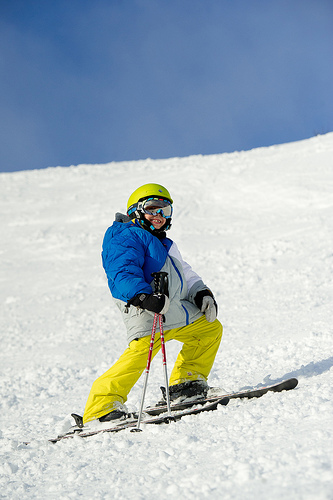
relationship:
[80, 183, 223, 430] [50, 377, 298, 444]
boy standing on skis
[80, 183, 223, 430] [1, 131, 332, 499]
boy in snow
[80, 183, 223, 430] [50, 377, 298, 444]
boy on skis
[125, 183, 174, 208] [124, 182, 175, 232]
helmet on head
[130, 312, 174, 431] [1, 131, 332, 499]
poles in snow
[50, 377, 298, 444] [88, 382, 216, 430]
skis attached to feet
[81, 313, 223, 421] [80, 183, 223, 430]
pants on boy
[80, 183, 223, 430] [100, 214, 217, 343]
boy wearing jacket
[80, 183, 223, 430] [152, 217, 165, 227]
boy has smile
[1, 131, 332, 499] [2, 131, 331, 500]
snow on ground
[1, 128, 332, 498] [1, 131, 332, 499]
hill covered with snow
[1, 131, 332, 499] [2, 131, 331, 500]
snow covering ground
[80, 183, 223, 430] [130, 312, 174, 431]
boy holding poles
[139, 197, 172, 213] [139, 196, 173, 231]
goggles on face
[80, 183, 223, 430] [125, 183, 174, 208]
boy wearing helmet